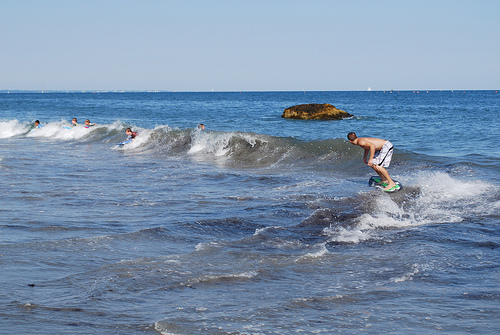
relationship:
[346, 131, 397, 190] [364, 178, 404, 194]
man on surf board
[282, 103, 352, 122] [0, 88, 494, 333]
island in middle of sea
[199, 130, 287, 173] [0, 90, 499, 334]
waves crashing in sea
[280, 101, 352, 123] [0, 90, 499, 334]
rock in sea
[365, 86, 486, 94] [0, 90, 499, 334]
boats in sea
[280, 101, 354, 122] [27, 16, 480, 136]
rock in distance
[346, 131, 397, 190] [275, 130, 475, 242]
man riding wave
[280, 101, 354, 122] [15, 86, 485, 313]
rock jutting out from water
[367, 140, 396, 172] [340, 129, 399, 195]
shorts worn by surfer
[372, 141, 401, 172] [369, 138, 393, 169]
stripe on shorts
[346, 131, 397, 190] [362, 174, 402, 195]
man on surfboard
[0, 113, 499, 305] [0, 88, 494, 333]
waves on sea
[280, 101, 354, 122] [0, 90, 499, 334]
rock in middle of sea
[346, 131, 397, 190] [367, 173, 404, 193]
man surfing on surf board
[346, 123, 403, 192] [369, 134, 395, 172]
man wearing shorts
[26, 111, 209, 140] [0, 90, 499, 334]
people surfing in sea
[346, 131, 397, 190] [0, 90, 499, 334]
man surfing in sea